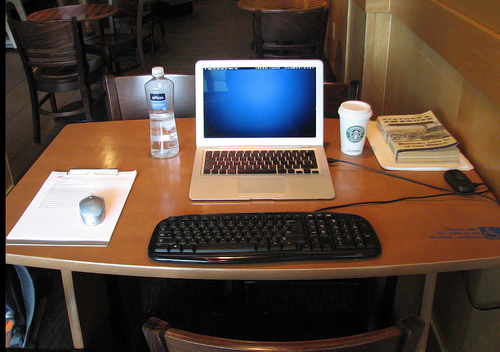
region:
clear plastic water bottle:
[138, 52, 182, 169]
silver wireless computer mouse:
[69, 178, 111, 236]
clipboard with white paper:
[6, 162, 139, 251]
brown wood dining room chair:
[5, 12, 110, 135]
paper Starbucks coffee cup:
[329, 81, 374, 166]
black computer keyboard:
[142, 205, 384, 270]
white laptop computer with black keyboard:
[181, 52, 336, 205]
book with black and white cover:
[372, 107, 464, 169]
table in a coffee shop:
[13, 95, 498, 347]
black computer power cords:
[323, 151, 498, 220]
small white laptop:
[161, 36, 360, 219]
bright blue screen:
[192, 44, 320, 145]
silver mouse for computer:
[58, 166, 118, 232]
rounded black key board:
[135, 197, 398, 273]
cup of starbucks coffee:
[327, 90, 379, 164]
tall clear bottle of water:
[114, 55, 198, 184]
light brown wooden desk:
[20, 66, 489, 312]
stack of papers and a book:
[350, 83, 489, 185]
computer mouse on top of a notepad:
[16, 151, 127, 254]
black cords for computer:
[295, 137, 486, 243]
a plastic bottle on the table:
[142, 62, 183, 160]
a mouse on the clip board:
[76, 188, 110, 228]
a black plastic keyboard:
[138, 206, 388, 270]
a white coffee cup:
[332, 95, 381, 160]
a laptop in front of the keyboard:
[181, 57, 336, 214]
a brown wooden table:
[0, 107, 497, 284]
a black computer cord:
[330, 154, 451, 192]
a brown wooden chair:
[136, 302, 436, 349]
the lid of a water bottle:
[149, 62, 166, 79]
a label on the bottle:
[147, 89, 167, 116]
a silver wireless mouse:
[80, 191, 105, 228]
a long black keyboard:
[142, 212, 382, 266]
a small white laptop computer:
[190, 61, 338, 201]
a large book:
[379, 106, 463, 163]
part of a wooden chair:
[106, 75, 196, 115]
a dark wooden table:
[0, 118, 498, 348]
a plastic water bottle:
[142, 67, 184, 159]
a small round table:
[25, 0, 119, 40]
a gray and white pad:
[2, 165, 137, 247]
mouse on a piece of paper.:
[77, 186, 102, 228]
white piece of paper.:
[40, 183, 64, 228]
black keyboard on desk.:
[190, 224, 355, 261]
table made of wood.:
[400, 215, 416, 251]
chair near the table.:
[227, 324, 388, 350]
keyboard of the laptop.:
[220, 150, 307, 168]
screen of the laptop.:
[212, 75, 302, 122]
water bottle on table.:
[145, 67, 174, 161]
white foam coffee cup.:
[338, 99, 369, 157]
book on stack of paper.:
[382, 109, 447, 156]